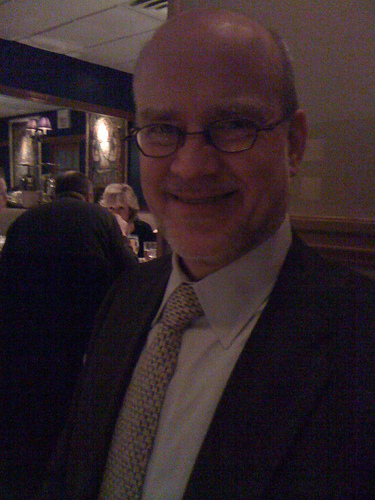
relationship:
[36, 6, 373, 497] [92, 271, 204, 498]
man wears tie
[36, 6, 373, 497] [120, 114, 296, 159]
man wears glasses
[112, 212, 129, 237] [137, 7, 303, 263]
napkin on face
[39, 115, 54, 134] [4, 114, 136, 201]
light on wall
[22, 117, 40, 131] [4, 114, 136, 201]
light on wall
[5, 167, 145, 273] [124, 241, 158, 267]
man front table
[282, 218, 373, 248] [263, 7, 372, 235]
trim along wall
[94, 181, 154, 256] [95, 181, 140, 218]
woman has hair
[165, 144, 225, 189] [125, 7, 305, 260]
nose on man's face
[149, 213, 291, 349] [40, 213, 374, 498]
collar on shirt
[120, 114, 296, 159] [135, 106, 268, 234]
glasses on face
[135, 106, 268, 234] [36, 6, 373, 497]
face of man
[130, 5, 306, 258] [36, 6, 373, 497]
head of man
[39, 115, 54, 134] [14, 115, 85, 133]
light on wall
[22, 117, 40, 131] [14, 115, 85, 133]
light on wall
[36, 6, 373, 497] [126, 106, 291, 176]
man wearing glasses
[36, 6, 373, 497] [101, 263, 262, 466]
man wearing shirt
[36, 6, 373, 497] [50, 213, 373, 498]
man wearing suit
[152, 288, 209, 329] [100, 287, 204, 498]
knot on tie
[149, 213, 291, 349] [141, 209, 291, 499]
collar on shirt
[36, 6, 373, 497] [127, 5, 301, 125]
man has balding head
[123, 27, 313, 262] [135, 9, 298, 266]
man's bald head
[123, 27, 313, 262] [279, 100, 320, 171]
man's left ear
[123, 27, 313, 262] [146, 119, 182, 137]
man's two eye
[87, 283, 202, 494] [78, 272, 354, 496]
tie and suit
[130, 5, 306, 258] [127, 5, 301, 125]
head with balding head